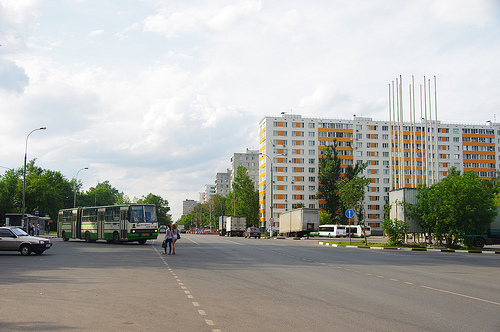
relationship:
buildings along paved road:
[196, 91, 469, 249] [162, 231, 228, 305]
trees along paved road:
[186, 150, 256, 230] [162, 231, 228, 305]